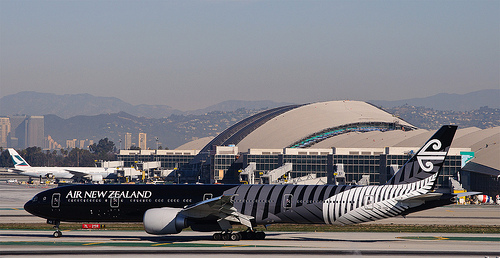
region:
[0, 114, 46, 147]
tall buildings seen in the background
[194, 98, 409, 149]
dome made of concrete and classes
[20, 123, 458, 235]
plane is black, grey and white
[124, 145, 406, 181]
building with large dark windows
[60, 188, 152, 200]
inscription on plane reads air new zealand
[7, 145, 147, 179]
white large plane in distance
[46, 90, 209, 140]
mountains seen in the background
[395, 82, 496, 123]
mountains seen in the background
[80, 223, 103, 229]
red artifact on side of runway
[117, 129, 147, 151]
tall buildings seen the background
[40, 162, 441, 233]
plane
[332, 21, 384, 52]
white clouds in blue sky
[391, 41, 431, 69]
white clouds in blue sky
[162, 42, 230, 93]
white clouds in blue sky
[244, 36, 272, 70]
white clouds in blue sky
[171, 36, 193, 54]
white clouds in blue sky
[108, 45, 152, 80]
white clouds in blue sky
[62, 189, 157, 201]
company name on side of aircraft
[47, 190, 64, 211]
black metal door on side of aircraft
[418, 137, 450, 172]
design on tail fin of aircraft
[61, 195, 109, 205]
row of small windows on black aircraft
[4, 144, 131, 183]
white aircraft parked on runway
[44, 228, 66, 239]
black landing wheels on aircraft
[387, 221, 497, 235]
grass growing on ground beside runway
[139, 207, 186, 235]
large white jet engine on aircraft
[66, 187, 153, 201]
"AIR NEW ZEALAND" on the plane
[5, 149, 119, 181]
mostly white plane in the background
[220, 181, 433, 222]
black and white stripes on plane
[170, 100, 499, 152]
domed airport behind planes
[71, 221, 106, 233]
red item underneath air new zealand plane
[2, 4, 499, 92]
hazy sky over airport and city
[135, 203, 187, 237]
port side engine of air new zealand plane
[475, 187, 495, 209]
red, white, and blue item in distance on lower right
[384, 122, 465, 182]
tail of air new zealand plane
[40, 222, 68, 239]
front wheels of air new zealand plane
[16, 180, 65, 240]
the nose of an airplane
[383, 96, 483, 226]
the tail part of an airplane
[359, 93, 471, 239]
the tail part of an airplane in black and white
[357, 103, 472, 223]
the tail of an airplane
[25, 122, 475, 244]
a black and white plane on the runway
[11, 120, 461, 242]
a black and white plane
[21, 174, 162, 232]
white letters on the side of the plane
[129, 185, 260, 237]
airplane's left wing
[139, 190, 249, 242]
the engine of an airplane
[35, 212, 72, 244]
front tires on an aeroplane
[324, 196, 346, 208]
Windows on an airplane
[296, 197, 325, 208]
Windows on an airplane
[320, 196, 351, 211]
Windows on an airplane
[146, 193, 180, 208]
Windows on an airplane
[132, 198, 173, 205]
Windows on an airplane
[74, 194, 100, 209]
Windows on an airplane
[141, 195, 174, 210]
Windows on an airplane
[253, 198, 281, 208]
Windows on an airplane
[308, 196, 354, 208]
Windows on an airplane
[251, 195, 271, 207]
Windows on an airplane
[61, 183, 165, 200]
air new zealand logo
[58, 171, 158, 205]
air new zealand logo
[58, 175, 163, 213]
air new zealand logo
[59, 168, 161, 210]
air new zealand logo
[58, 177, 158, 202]
air new zealand logo